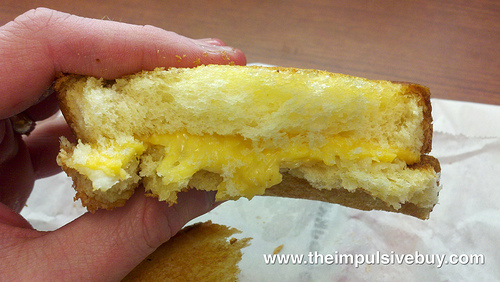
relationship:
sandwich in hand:
[64, 63, 449, 214] [3, 3, 245, 281]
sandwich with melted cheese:
[64, 63, 449, 214] [81, 126, 423, 193]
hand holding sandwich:
[3, 3, 245, 281] [64, 63, 449, 214]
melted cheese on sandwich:
[81, 126, 423, 193] [64, 63, 449, 214]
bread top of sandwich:
[52, 65, 428, 136] [64, 63, 449, 214]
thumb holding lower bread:
[56, 185, 239, 269] [62, 165, 449, 220]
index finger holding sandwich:
[0, 8, 251, 87] [64, 63, 449, 214]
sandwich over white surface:
[64, 63, 449, 214] [23, 65, 497, 281]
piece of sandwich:
[71, 78, 133, 186] [64, 63, 449, 214]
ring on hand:
[7, 109, 38, 143] [3, 3, 245, 281]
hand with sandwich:
[3, 3, 245, 281] [64, 63, 449, 214]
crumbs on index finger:
[138, 48, 234, 67] [0, 8, 251, 87]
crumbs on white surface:
[237, 213, 313, 266] [23, 65, 497, 281]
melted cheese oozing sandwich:
[81, 126, 423, 193] [64, 63, 449, 214]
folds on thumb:
[0, 203, 59, 242] [56, 185, 239, 269]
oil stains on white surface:
[224, 197, 323, 247] [23, 65, 497, 281]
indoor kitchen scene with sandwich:
[1, 0, 498, 280] [64, 63, 449, 214]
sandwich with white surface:
[64, 63, 449, 214] [23, 65, 497, 281]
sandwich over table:
[64, 63, 449, 214] [0, 0, 499, 107]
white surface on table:
[23, 65, 497, 281] [0, 0, 499, 107]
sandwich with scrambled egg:
[64, 63, 449, 214] [69, 131, 249, 189]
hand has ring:
[3, 3, 245, 281] [7, 109, 38, 143]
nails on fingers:
[207, 38, 237, 53] [144, 26, 247, 67]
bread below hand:
[137, 225, 253, 282] [3, 3, 245, 281]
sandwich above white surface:
[64, 63, 449, 214] [23, 65, 497, 281]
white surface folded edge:
[23, 65, 497, 281] [428, 91, 499, 147]